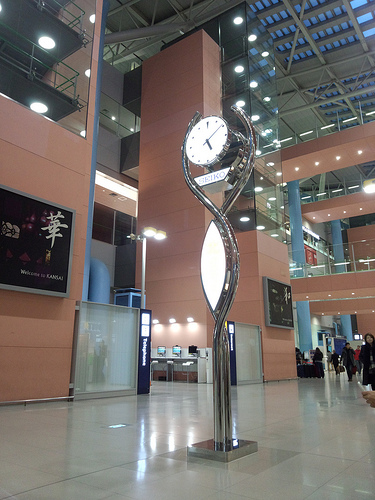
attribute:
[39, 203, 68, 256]
writing — asian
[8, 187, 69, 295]
wallpicture — black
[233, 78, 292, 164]
screen — grey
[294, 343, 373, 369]
people — waiting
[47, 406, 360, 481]
floor — white, shiny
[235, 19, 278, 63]
lights — three, white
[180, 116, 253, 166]
clock — silver, white, modern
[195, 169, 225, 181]
seiko — silver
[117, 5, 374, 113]
ceiling — blue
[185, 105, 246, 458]
clock — artstructure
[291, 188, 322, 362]
beam — blue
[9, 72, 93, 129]
rail — glass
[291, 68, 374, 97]
girders — metal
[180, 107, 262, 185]
clocktower — decorative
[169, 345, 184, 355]
computer monitors — computermonitors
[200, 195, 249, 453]
frame — steel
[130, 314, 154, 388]
towers — blue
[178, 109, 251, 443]
bar — metal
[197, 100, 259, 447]
bar — metal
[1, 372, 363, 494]
floor — tile